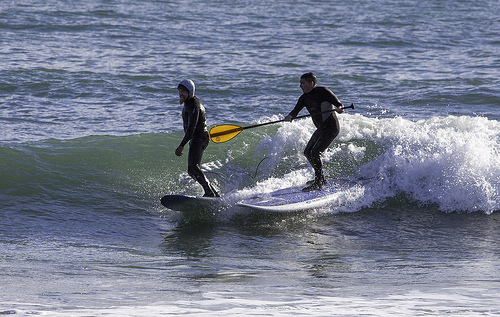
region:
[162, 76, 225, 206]
man wearing a blue helmet while surfing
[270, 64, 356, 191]
man wearing a black water suit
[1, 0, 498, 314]
beautiful blue green ocean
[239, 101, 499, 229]
white crested wave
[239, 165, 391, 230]
white and blue sur board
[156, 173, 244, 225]
front end of a blue surf board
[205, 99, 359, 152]
orange paddle with a black handle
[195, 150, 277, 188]
black spiraled safety cord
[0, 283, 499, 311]
white foam floating on top of the water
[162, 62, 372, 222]
two surfers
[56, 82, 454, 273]
the wave is small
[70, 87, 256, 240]
the wave is small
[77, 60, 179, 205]
the wave is small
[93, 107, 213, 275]
the wave is small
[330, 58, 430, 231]
the wave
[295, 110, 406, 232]
the wave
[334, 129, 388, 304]
the wave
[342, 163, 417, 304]
the wave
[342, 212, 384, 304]
the wave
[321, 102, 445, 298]
the wave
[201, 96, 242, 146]
paddle held by surfer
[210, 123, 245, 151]
orange paddle held by surfer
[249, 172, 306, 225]
surfboard ridden by male surfer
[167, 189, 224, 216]
surfboard ridden by male surfer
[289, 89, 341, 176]
surfer wearing black wet suit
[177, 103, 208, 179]
surfer wearing black wet suit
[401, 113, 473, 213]
white foam in green ocean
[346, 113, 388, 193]
white foam in green ocean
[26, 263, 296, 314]
white foam in green ocean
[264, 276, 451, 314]
white foam in green ocean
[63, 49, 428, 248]
a pair of people surfing near each other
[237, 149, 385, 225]
a blue and white surfboard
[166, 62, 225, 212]
a man wearing a helmet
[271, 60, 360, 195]
man in a black and grey wetsuit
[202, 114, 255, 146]
a bright orange paddle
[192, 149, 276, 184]
a long black leash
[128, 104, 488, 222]
a wave crashing on surfers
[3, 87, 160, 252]
some light green water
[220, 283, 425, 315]
some small bubbles in the water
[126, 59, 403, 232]
a pair of wet people